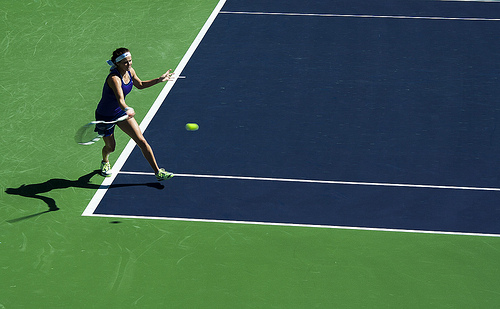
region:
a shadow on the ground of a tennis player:
[1, 170, 164, 220]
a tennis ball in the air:
[180, 115, 205, 132]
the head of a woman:
[106, 45, 143, 70]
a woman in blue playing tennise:
[88, 46, 185, 192]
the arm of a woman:
[133, 68, 170, 92]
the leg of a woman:
[127, 124, 177, 184]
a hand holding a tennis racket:
[70, 107, 140, 154]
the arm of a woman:
[113, 79, 137, 119]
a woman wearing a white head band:
[103, 43, 142, 77]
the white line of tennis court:
[165, 210, 400, 237]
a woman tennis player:
[11, 21, 286, 236]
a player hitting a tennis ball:
[35, 35, 325, 225]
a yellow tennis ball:
[180, 120, 200, 135]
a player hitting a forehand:
[60, 40, 235, 185]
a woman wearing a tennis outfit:
[68, 43, 177, 197]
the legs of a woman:
[98, 123, 170, 184]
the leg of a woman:
[95, 129, 121, 181]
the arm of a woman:
[103, 73, 133, 122]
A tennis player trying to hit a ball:
[71, 45, 177, 183]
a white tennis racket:
[70, 110, 125, 146]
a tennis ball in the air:
[182, 120, 197, 130]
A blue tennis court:
[80, 0, 496, 235]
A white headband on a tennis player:
[106, 50, 133, 66]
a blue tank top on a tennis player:
[95, 65, 133, 113]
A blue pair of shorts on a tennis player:
[91, 105, 130, 133]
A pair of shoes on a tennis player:
[98, 161, 175, 183]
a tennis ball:
[183, 120, 199, 130]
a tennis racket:
[73, 113, 130, 147]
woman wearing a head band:
[45, 30, 235, 200]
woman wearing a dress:
[76, 35, 196, 200]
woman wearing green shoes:
[83, 43, 178, 239]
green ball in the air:
[160, 107, 201, 133]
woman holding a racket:
[80, 40, 180, 195]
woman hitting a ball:
[73, 37, 178, 184]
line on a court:
[181, 210, 309, 233]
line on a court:
[210, 170, 280, 183]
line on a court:
[180, 13, 215, 60]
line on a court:
[355, 9, 435, 27]